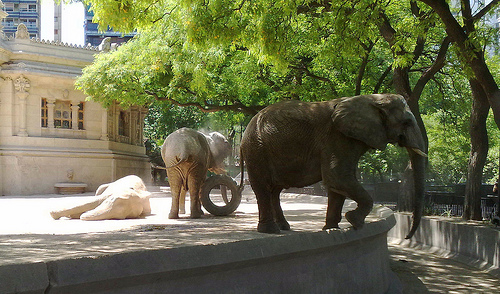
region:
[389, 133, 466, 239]
the trunk of a elephant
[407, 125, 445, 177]
the tusk of a elephant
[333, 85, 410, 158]
the ear of a elephant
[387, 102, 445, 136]
the eye of a elephant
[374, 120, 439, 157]
the mouth of a elephant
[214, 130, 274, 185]
the tail of a elephant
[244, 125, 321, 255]
the back legs of a elephant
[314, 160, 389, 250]
the front legs of a elephant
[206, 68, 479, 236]
a big grey elephant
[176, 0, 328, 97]
green leaves on a tree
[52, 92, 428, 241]
Three elephants at the zoo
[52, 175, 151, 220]
the elephant laying on the ground in the sun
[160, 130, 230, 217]
an elephant playing with a giant tire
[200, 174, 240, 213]
a giant truck tire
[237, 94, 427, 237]
elephant on the right on the ledge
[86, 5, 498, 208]
several trees near the elephants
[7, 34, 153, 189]
white building behind the elephants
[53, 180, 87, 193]
bench next to the building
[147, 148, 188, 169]
tail of the elephant by the tire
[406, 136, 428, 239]
trunk of the elephant on the edge of the drop off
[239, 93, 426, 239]
A large elephant standing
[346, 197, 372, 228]
Foot is raise off ground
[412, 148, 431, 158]
The elephant has tusks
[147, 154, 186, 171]
Tail swishing to left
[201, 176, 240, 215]
A black rubber tire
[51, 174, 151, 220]
Elephant is lying down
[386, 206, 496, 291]
A moat to keep the elephants in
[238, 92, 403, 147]
Sunlight shining on elephant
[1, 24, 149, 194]
The building is white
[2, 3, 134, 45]
Buildings in the distance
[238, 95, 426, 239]
A large dark grey elephant going over the edge.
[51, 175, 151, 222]
A light colored elephant lying down.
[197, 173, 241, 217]
A large black tire.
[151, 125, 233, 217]
A large grey elephant playing with a tire.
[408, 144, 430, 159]
White tusk on a dark grey elephant.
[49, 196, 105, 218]
Back extended light colore elephant lying down.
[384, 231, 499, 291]
Walkway below the elephants.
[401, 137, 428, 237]
A dark grey elephant over the edge.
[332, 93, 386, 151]
A dark grey right ear of an elephant going over an edge.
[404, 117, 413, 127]
The right eye of a dark elephant.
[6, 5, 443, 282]
elephants in front the building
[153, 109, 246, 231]
elephant is playing with a tire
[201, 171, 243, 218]
a black tire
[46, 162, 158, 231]
elephant lying on the floor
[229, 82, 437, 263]
elephant on the edge of a platform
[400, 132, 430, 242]
long trunk of elephant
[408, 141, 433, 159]
a white tusk of elephant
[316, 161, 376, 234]
front feet of elephant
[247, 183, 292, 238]
back feet of elephant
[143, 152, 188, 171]
tail of elephant